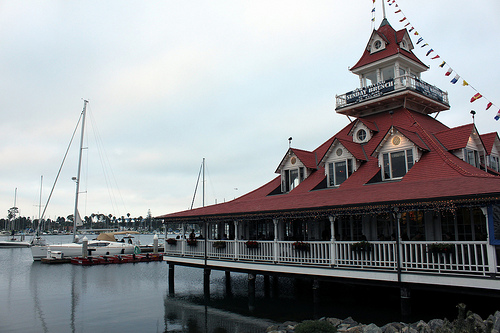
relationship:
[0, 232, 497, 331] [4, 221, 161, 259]
water under boats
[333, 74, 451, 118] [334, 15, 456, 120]
platform on building top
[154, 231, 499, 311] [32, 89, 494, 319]
porch on building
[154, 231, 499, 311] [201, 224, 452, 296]
porch has railing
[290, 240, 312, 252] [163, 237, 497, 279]
flowers hanging on railing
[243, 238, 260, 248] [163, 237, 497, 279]
flowers hanging on railing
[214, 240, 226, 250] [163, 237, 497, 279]
flowers hanging on railing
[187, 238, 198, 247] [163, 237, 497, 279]
flowers hanging on railing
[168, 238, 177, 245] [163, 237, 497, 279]
flowers hanging on railing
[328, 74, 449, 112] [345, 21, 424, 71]
railing surrounds roof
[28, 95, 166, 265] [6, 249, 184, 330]
boat in water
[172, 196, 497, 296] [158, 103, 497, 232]
building has roof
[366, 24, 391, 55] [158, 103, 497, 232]
peak on roof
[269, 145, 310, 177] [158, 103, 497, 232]
peak on roof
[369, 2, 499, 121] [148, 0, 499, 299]
flags hanging from building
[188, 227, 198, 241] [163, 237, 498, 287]
person standing on porch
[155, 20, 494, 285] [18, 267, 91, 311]
red building on water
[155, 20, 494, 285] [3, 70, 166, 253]
red building in harbor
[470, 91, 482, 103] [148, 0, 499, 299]
flag hanging on building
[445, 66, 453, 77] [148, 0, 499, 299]
flag hanging on building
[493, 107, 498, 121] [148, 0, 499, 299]
flag hanging on building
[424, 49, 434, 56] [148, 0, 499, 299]
flag hanging on building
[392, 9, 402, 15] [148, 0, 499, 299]
flag hanging on building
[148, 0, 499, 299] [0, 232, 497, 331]
building on water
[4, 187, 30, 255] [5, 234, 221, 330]
sailboat mocked harbor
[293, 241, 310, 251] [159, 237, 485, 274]
flower box on rail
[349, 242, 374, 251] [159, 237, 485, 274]
flower box on rail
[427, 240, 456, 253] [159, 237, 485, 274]
flower box on rail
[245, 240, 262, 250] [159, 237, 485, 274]
flower box on rail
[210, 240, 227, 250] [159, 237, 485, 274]
flower box on rail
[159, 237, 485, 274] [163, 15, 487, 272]
rail on building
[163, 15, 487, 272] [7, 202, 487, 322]
building on harbor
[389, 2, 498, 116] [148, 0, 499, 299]
pendants hanging from building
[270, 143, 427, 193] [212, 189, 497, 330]
windows on building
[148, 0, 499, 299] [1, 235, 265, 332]
building off water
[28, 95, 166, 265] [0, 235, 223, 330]
boat in water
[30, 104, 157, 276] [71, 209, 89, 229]
boat has sail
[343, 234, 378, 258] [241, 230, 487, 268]
flowers on gate